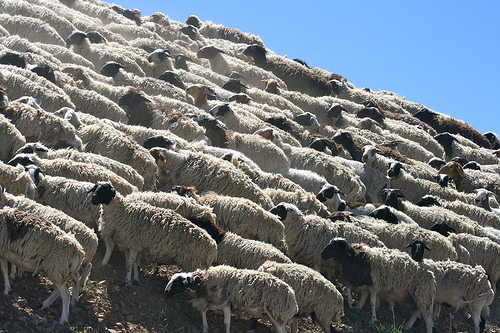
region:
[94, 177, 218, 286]
sheep is next to sheep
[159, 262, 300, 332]
sheep is next to sheep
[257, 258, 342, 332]
sheep is next to sheep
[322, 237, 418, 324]
sheep is next to sheep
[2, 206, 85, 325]
sheep is next to sheep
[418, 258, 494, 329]
sheep is next to sheep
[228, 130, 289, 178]
sheep is next to sheep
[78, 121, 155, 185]
sheep is next to sheep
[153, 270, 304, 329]
A black head white dirty sheep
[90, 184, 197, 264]
A black head white dirty sheep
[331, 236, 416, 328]
A black head white dirty sheep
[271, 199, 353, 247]
A black head white dirty sheep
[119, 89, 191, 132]
A black head white dirty sheep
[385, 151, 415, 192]
A black head white dirty sheep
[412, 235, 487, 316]
A black head white dirty sheep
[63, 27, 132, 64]
A black head white dirty sheep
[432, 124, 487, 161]
A black head white dirty sheep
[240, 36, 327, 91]
A black head brown dirty sheep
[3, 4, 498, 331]
A large herd of sheep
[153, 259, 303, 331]
A sheep near the camera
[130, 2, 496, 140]
A patch of blue sky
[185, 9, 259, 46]
A sheep in the distance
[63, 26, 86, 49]
The head of a sheep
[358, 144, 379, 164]
A sheep's head looking at the camera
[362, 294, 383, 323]
The leg of a sheep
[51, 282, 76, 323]
A sheep's hind leg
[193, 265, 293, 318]
Wool on a sheep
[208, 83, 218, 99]
The ear of a sheep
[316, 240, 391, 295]
sheep has black face and neck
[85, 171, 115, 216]
animal is looking towards camera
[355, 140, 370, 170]
animal has a white face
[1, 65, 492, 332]
sheep are gathered together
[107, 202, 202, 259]
their coats are white and thick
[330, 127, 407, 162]
there is a brown animal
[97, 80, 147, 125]
head is black and brown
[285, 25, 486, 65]
sky is clear and blue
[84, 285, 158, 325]
twigs and dirt on the ground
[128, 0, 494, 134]
Blue sky with no clouds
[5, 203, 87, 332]
Sheep with brown spot on back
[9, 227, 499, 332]
Brown rocky ground with little grass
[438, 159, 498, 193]
Sheep with brown head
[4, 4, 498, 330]
Group of sheep walking up a hill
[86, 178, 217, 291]
Sheep with black head and white coat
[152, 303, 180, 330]
Small tuft of green grass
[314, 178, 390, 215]
Sheep with white face and black spots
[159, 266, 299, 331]
Sheep with a dirty coat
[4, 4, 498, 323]
Hill covered with many sheep